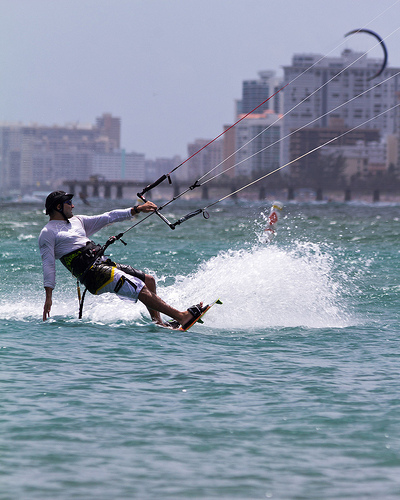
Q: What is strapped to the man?
A: Lines for the kite.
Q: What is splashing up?
A: Water.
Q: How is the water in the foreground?
A: Calm.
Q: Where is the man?
A: In the water.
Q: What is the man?
A: Wet.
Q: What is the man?
A: Wet.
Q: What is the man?
A: Wet.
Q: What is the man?
A: Wet.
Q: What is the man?
A: Wet.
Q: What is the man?
A: Wet.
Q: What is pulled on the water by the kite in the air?
A: The man.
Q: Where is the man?
A: On the water.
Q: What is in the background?
A: Buildings.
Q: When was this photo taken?
A: During daylight hours.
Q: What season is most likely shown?
A: Summer.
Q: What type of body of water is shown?
A: A lake.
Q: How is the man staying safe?
A: Wearing safety gear.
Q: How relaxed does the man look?
A: The man looks very relaxed.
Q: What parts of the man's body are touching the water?
A: Hand & feet.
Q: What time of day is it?
A: Daytime.